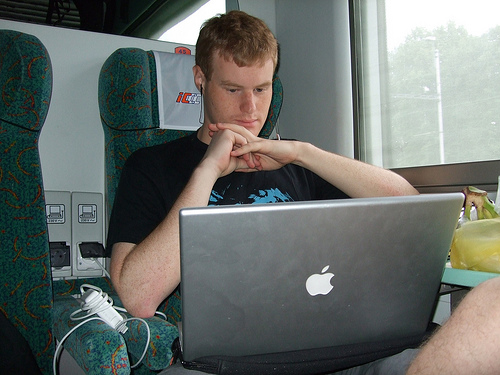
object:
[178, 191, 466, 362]
cover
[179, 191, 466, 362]
laptop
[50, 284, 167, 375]
cord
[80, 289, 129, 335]
charger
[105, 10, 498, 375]
man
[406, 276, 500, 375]
leg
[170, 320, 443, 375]
laptop case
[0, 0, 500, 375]
bus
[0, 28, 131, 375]
seat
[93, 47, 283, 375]
seat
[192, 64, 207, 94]
ear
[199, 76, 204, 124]
earbud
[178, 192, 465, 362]
back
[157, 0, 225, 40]
window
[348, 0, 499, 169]
window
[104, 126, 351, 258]
shirt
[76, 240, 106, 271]
port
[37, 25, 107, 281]
middle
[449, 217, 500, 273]
container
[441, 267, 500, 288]
counter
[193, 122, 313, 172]
hand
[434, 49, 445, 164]
pole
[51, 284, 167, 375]
charging cord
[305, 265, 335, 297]
apple logo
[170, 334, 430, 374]
lap